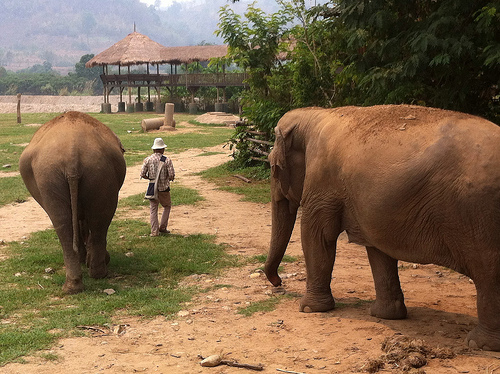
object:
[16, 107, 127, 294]
elephant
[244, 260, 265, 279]
rock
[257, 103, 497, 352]
elephant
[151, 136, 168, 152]
hat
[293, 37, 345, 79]
leave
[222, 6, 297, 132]
tree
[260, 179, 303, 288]
trunk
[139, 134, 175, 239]
man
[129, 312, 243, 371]
ground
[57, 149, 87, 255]
tail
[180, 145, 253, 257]
walkway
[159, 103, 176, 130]
pillar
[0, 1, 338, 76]
mountain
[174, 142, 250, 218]
path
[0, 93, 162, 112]
fence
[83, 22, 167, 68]
roof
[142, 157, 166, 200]
bag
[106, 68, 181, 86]
deck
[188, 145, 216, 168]
sand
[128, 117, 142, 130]
grass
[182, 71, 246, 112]
bridge